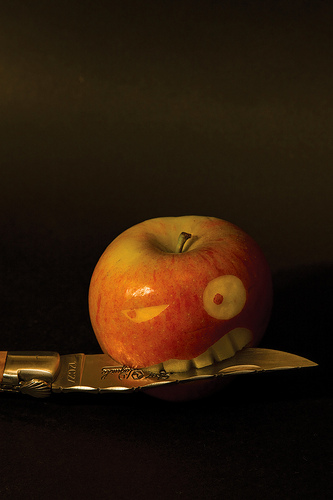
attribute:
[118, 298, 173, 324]
apple — squinty eye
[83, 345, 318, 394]
blade — knife's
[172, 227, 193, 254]
stem — apple's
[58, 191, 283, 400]
apple — red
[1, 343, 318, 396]
pocket knife — old